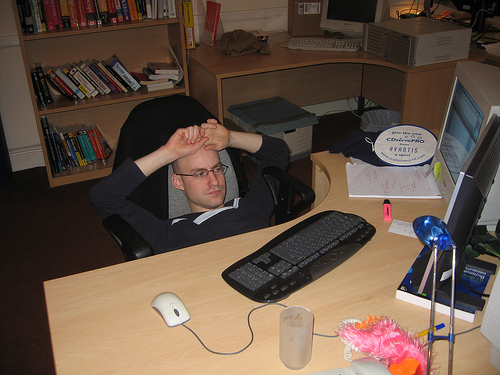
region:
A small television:
[429, 61, 498, 198]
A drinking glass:
[274, 306, 319, 366]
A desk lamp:
[407, 207, 476, 373]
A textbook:
[396, 230, 486, 322]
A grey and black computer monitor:
[405, 118, 496, 293]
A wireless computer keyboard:
[220, 206, 370, 301]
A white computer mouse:
[135, 290, 216, 340]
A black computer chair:
[95, 120, 290, 250]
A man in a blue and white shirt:
[95, 120, 291, 243]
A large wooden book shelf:
[8, 0, 210, 180]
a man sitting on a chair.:
[106, 86, 302, 256]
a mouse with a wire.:
[143, 288, 498, 360]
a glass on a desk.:
[270, 303, 332, 374]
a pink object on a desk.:
[334, 304, 437, 374]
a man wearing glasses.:
[161, 158, 228, 193]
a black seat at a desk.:
[93, 85, 237, 260]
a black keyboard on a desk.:
[215, 203, 391, 320]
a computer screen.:
[375, 111, 497, 323]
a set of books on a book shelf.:
[31, 25, 176, 117]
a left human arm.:
[191, 100, 278, 167]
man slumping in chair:
[107, 127, 312, 249]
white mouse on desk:
[146, 288, 198, 333]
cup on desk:
[274, 301, 325, 373]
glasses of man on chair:
[171, 163, 231, 183]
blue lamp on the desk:
[412, 216, 464, 373]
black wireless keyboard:
[204, 201, 396, 301]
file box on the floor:
[233, 87, 322, 161]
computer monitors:
[430, 53, 499, 298]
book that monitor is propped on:
[399, 221, 491, 326]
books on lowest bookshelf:
[33, 116, 124, 183]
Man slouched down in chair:
[81, 95, 298, 250]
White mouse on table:
[147, 288, 192, 328]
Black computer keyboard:
[220, 206, 378, 305]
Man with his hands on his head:
[144, 114, 256, 209]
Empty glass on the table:
[273, 303, 316, 370]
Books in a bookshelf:
[15, 0, 192, 191]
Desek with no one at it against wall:
[186, 0, 474, 145]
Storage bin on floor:
[229, 95, 318, 160]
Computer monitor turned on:
[430, 65, 494, 193]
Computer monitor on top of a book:
[394, 113, 499, 323]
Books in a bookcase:
[4, 5, 165, 162]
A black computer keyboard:
[221, 205, 379, 295]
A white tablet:
[338, 157, 441, 206]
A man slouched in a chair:
[90, 90, 305, 232]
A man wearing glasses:
[166, 144, 245, 223]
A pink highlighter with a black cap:
[370, 197, 397, 227]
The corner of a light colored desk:
[39, 252, 152, 374]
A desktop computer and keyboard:
[309, 0, 382, 65]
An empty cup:
[266, 301, 324, 371]